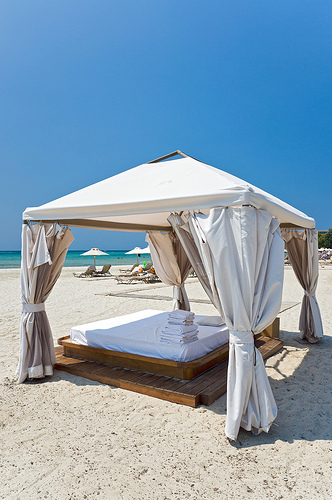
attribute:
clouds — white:
[223, 125, 325, 183]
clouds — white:
[237, 89, 274, 157]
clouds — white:
[126, 41, 249, 98]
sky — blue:
[172, 27, 236, 86]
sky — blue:
[3, 4, 331, 153]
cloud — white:
[95, 104, 159, 125]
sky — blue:
[74, 36, 276, 117]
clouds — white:
[2, 1, 48, 13]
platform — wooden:
[88, 325, 250, 437]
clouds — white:
[63, 28, 136, 130]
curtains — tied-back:
[25, 210, 329, 450]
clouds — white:
[129, 98, 256, 180]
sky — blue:
[1, 1, 321, 265]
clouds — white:
[17, 56, 221, 186]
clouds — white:
[3, 93, 305, 217]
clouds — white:
[20, 124, 235, 218]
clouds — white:
[19, 66, 200, 170]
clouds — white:
[16, 79, 242, 175]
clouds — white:
[193, 39, 296, 109]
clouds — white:
[13, 39, 175, 154]